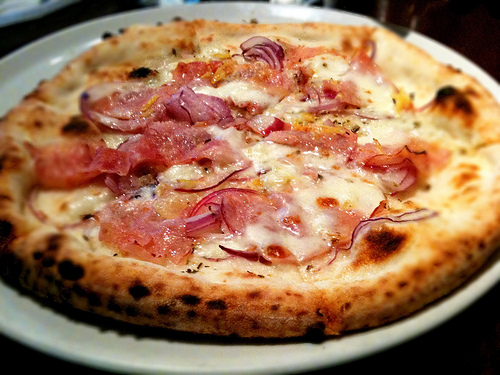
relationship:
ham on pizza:
[164, 87, 211, 128] [5, 12, 494, 345]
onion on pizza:
[356, 194, 403, 243] [50, 40, 405, 301]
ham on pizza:
[95, 78, 219, 149] [5, 12, 494, 345]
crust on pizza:
[132, 260, 217, 332] [113, 115, 298, 302]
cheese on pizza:
[166, 190, 321, 245] [17, 13, 462, 280]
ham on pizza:
[349, 133, 429, 195] [5, 12, 494, 345]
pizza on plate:
[5, 12, 494, 345] [5, 4, 497, 370]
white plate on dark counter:
[33, 308, 202, 373] [373, 310, 497, 374]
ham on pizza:
[95, 116, 255, 195] [22, 48, 449, 292]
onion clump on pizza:
[240, 31, 288, 72] [22, 48, 449, 292]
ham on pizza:
[146, 88, 219, 125] [7, 21, 499, 373]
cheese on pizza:
[11, 35, 488, 287] [5, 12, 494, 345]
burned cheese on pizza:
[422, 82, 487, 134] [5, 12, 494, 345]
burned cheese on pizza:
[354, 219, 411, 257] [5, 12, 494, 345]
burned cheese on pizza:
[117, 57, 164, 83] [5, 12, 494, 345]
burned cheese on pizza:
[49, 107, 106, 143] [5, 12, 494, 345]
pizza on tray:
[40, 36, 433, 300] [3, 3, 499, 373]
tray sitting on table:
[3, 3, 499, 373] [3, 1, 499, 372]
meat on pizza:
[52, 115, 237, 185] [5, 12, 494, 345]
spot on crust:
[0, 213, 20, 251] [0, 192, 326, 344]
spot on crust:
[29, 231, 65, 276] [0, 192, 326, 344]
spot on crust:
[52, 255, 89, 285] [0, 192, 326, 344]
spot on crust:
[125, 276, 154, 305] [0, 192, 326, 344]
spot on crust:
[112, 298, 154, 321] [0, 192, 326, 344]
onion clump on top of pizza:
[240, 31, 288, 72] [234, 28, 283, 72]